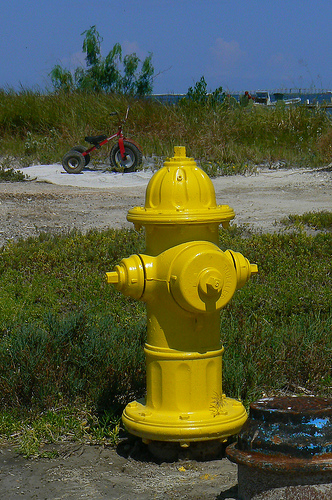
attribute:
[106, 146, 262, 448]
hydrant — yellow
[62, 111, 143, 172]
tricycle — red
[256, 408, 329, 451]
paint — blue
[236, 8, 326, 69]
sky — blue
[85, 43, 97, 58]
leaves — green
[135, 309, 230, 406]
pipe — yellow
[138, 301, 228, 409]
pipe — yellow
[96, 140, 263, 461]
fire hydrant — bright yellow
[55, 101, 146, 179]
tricycle — red, black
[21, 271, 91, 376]
grass — green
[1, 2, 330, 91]
sky — cloudy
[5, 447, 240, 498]
paved — grey, concrete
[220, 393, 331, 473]
top — rusty, blue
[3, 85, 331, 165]
grass — tall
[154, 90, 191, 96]
water — blue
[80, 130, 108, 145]
seat — black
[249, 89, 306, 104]
boat — white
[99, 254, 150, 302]
pipe — yellow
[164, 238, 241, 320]
pipe — yellow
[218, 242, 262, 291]
pipe — yellow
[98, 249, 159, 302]
pipe — yellow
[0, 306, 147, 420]
weeds — green